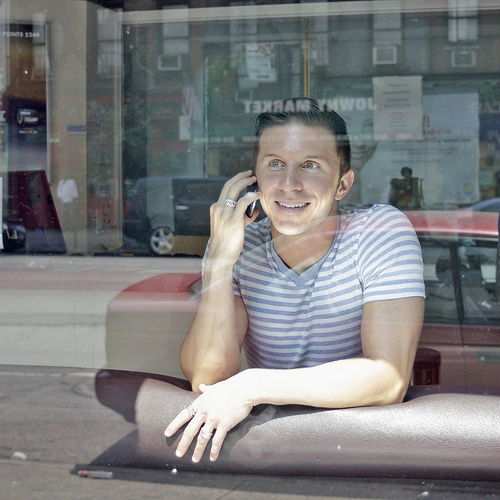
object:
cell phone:
[245, 166, 259, 218]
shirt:
[201, 202, 427, 369]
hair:
[338, 118, 350, 149]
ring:
[199, 427, 213, 439]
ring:
[223, 198, 237, 208]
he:
[163, 96, 426, 463]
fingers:
[163, 383, 229, 464]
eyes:
[268, 159, 322, 172]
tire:
[146, 225, 177, 256]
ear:
[334, 169, 355, 201]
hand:
[163, 377, 253, 464]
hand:
[208, 169, 263, 264]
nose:
[277, 169, 303, 192]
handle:
[475, 348, 499, 364]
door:
[452, 243, 500, 396]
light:
[124, 200, 131, 220]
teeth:
[278, 202, 307, 209]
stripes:
[261, 280, 315, 369]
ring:
[185, 403, 197, 417]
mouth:
[274, 198, 312, 214]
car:
[103, 208, 500, 434]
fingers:
[210, 169, 261, 225]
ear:
[250, 163, 254, 189]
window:
[0, 0, 500, 498]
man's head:
[253, 97, 355, 237]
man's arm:
[263, 231, 426, 411]